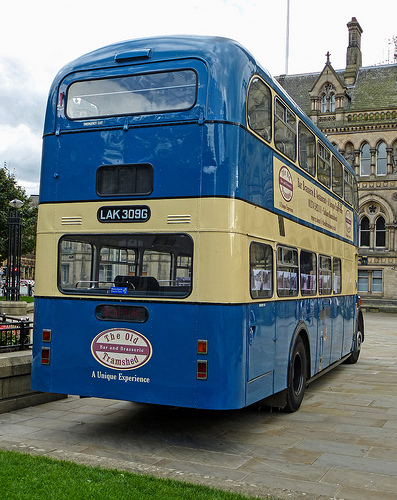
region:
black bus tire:
[268, 333, 319, 420]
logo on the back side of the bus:
[76, 324, 162, 392]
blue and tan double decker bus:
[25, 38, 378, 402]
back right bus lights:
[190, 337, 219, 399]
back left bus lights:
[31, 319, 60, 376]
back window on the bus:
[38, 62, 196, 126]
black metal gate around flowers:
[1, 313, 27, 358]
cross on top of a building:
[319, 48, 338, 66]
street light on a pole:
[6, 186, 33, 294]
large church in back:
[296, 28, 395, 317]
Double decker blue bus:
[34, 32, 382, 404]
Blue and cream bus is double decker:
[39, 43, 378, 413]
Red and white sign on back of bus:
[72, 321, 160, 391]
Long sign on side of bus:
[266, 159, 366, 246]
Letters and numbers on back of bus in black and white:
[87, 201, 164, 233]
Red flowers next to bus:
[0, 319, 18, 348]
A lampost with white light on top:
[8, 190, 28, 311]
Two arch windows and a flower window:
[353, 198, 392, 259]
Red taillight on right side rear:
[192, 333, 214, 359]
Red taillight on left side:
[34, 323, 54, 345]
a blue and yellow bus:
[28, 34, 367, 422]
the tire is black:
[275, 330, 312, 416]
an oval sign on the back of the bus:
[84, 325, 153, 370]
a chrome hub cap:
[351, 329, 368, 351]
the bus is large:
[27, 33, 374, 430]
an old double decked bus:
[26, 31, 369, 421]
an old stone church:
[267, 14, 396, 312]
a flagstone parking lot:
[3, 299, 394, 498]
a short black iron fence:
[0, 309, 31, 352]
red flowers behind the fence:
[0, 322, 18, 336]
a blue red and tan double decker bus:
[29, 35, 365, 415]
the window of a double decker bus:
[247, 239, 277, 296]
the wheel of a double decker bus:
[273, 334, 313, 412]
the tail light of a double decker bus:
[196, 359, 207, 377]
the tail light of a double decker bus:
[40, 347, 50, 362]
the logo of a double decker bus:
[87, 328, 148, 369]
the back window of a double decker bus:
[56, 230, 194, 298]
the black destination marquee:
[96, 207, 145, 222]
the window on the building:
[357, 268, 382, 292]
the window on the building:
[360, 212, 372, 247]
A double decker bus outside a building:
[32, 30, 388, 437]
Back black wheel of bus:
[281, 341, 316, 415]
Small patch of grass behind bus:
[2, 449, 195, 498]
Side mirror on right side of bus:
[357, 250, 370, 270]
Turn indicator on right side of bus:
[355, 289, 363, 309]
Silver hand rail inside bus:
[80, 270, 136, 296]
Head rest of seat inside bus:
[115, 269, 158, 292]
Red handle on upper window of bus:
[50, 83, 68, 118]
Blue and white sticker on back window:
[101, 282, 132, 300]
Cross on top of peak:
[320, 51, 337, 64]